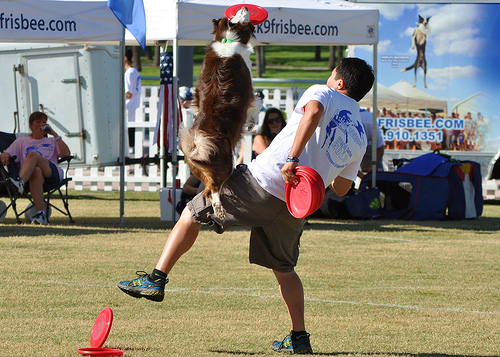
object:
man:
[118, 57, 374, 356]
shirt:
[246, 83, 366, 202]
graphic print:
[321, 110, 364, 168]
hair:
[334, 58, 374, 102]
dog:
[178, 7, 263, 232]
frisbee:
[225, 4, 267, 26]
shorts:
[186, 167, 305, 273]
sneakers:
[117, 274, 167, 301]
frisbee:
[78, 348, 122, 357]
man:
[124, 49, 141, 153]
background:
[0, 191, 500, 357]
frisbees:
[285, 172, 315, 218]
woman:
[0, 111, 70, 225]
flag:
[152, 52, 182, 153]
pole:
[159, 109, 164, 187]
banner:
[179, 3, 377, 45]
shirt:
[4, 135, 64, 182]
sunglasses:
[267, 117, 282, 124]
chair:
[0, 133, 73, 223]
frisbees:
[90, 308, 113, 349]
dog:
[400, 14, 432, 88]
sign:
[376, 0, 499, 150]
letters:
[254, 19, 339, 37]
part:
[191, 191, 211, 214]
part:
[140, 290, 162, 296]